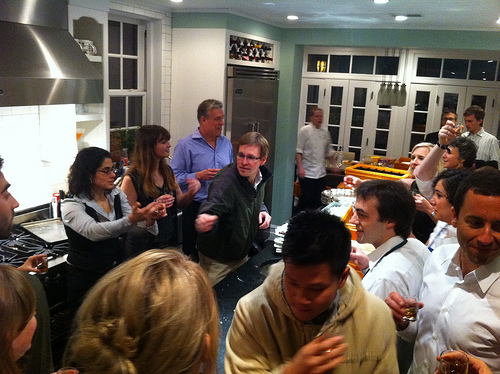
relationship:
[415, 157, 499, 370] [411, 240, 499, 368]
man wearing shirt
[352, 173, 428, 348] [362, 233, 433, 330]
man wearing shirt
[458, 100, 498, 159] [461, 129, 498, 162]
man wearing shirt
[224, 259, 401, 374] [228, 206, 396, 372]
hoodie on man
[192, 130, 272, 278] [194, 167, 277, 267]
man wearing jacket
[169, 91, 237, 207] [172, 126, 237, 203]
man wearing shirt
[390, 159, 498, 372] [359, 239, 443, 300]
man wearing shirt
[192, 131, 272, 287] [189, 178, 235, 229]
man extending arm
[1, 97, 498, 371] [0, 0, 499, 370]
people in kitchen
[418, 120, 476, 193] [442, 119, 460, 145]
person raising hand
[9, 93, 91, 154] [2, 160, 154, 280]
light above stove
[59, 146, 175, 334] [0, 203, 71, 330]
lady in front of stove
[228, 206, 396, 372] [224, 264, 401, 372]
man wearing hoodie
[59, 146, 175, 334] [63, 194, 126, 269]
lady wearing vest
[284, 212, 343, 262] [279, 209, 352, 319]
hair on head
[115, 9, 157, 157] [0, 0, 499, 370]
window in kitchen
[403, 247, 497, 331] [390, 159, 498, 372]
shirt on man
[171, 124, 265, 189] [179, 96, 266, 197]
shirt on man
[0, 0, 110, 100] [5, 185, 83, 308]
hood over stove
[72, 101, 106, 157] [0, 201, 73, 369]
shelves next to stove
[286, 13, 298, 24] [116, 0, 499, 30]
light on ceiling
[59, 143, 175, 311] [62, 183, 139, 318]
lady in dress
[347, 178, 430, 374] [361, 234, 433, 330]
man in shirt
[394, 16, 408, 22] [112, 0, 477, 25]
ceiling light in ceiling